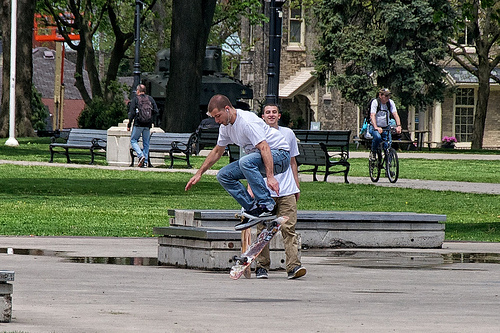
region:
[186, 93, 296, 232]
Skateboarder in the air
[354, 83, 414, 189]
Man riding bicycle on sidewalk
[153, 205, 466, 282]
Concrete benches with stone tops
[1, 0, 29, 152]
White light post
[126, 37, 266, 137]
Large dark grey metal tank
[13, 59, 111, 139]
Red brick building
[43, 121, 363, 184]
Metal and wood park benches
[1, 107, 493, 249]
Well manicured green lawns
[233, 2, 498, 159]
Large stone building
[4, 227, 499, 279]
Water on the concrete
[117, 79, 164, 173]
Man carry a backpack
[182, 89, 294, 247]
Man jumps in the air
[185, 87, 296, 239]
Man wears white t-shirt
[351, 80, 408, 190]
Man driving a bike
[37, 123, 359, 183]
Benches in the park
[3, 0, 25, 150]
White pole in the street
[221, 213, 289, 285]
Skateboard is upside down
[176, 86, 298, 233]
Man is crouched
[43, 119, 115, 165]
Bench is green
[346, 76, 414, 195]
Man wears a cap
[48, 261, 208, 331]
Gray cement sidewalk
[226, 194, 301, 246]
Black shoes on a man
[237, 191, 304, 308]
Brown pants on a man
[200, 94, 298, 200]
White shirt on a man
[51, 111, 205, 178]
Benches by a sidewalk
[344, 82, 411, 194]
Bike on a sidewalk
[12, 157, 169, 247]
Grass in a park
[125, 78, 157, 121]
Backpack on a man's back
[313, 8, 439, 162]
Tree in a park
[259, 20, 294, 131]
Light pole in a park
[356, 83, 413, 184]
Man riding a bike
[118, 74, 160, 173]
Balding man walking on sidewalk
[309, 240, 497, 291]
Large puddle on the ground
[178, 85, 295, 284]
Man performing a skateboarding trick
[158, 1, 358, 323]
Two skateboarders in the park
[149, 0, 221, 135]
Trunk of a very large tree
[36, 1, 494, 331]
People in a park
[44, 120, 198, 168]
Two park benches with a stone pedestal between them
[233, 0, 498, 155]
Stone building with beige trim and a flower pot in front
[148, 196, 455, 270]
Stone and concrete benches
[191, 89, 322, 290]
skateboarding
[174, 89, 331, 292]
two men skateboarding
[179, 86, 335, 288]
two skateboarders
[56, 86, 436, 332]
two skateboarders in a park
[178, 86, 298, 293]
a man doing a trick on a skateboard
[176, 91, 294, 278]
the skateboarder is in the air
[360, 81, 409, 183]
a person riding a bicycle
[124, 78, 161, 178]
a man wearing a backpack is walking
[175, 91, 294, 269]
the skateboarder doing the trick is wearing jeans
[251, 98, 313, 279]
a man watches the other man on the skateboard